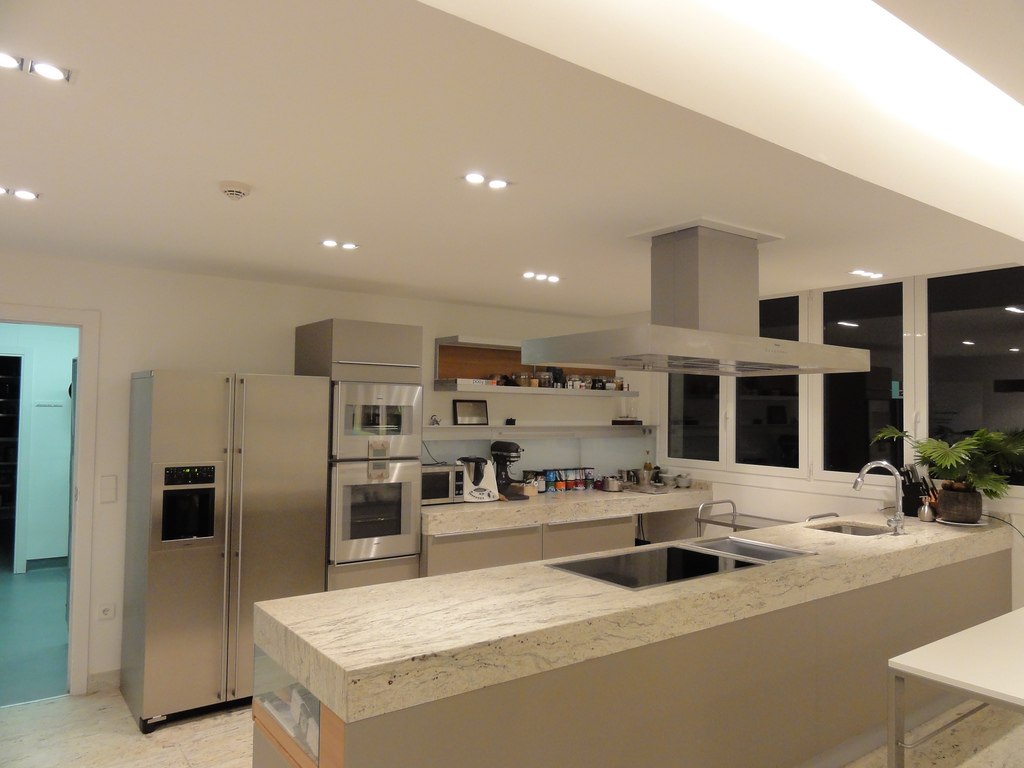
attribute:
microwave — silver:
[419, 462, 470, 504]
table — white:
[887, 599, 1021, 765]